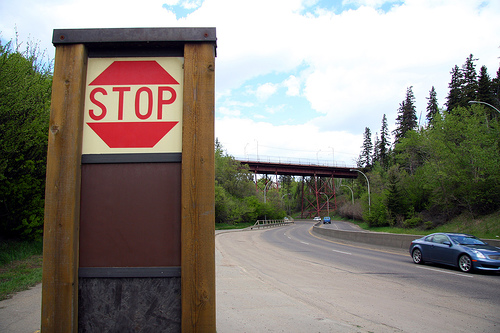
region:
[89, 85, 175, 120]
the word stop on a sign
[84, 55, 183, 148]
an unusual stop sign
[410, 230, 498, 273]
a black compact car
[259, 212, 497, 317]
a curving highway road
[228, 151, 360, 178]
a bridge overpass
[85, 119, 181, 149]
a four sided design on a sign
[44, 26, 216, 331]
a wooden sign post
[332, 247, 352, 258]
a dotted white line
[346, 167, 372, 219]
a silver metal street light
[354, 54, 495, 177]
tall pines on the side of the hill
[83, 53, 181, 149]
Stop sign next to the road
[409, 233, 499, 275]
Blue car on the road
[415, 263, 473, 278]
White traffic line next to the blue car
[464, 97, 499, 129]
Light post next to the road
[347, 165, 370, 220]
Light post next to the road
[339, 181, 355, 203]
Light post next to the road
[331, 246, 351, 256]
White line on the road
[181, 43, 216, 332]
Wood beam next to the stop sign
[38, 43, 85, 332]
Wood beam next to the stop sign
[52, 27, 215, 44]
metal bar on top of the stop sign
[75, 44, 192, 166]
sign at top of post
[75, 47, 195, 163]
sign on pole reads stop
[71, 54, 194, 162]
stop sign is red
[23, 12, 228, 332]
wooden post holds sign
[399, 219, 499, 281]
car driving on road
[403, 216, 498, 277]
car on road is blue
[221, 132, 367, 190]
bridge over road way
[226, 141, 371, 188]
bridge over road is red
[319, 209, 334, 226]
truck on opposite lane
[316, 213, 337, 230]
truck in right lane is blue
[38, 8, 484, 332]
car driving along highway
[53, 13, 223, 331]
stop sign on side of road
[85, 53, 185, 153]
stop sign is red and white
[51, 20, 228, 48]
top of sign post is metal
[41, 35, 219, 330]
outside of sign post is wooden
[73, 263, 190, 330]
bottom of sign post is metal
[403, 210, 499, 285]
blue car on roadway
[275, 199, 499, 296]
cars travelling down highway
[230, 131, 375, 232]
bridge over highway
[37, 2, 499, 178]
white puffy clouds in sky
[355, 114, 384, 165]
tall trees in a park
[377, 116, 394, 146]
tall trees in a park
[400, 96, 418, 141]
tall trees in a park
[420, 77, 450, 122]
tall trees in a park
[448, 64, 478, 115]
tall trees in a park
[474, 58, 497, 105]
tall trees in a park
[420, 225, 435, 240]
window of a car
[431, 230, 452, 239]
window of a car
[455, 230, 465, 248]
window of a car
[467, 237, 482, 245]
window of a car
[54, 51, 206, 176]
stop sign above the ground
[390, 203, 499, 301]
car on the street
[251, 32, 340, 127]
white clouds in a blue sky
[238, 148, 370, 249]
a red metal bridge over a highway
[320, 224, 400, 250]
a concrete barrier wall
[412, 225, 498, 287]
a blue vehicle on a highway